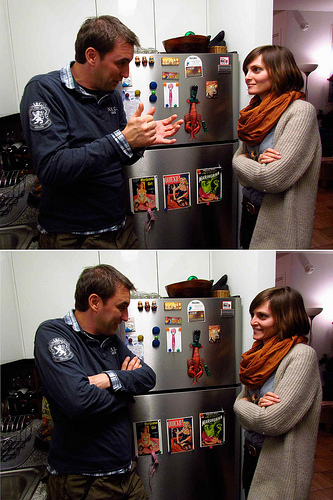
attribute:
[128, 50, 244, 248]
fridge — stainless steel, silver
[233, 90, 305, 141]
scarf — brown, burnt orange, loose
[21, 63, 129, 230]
shirt — blue, long-sleeve, dark blue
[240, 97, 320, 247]
cardigan — sand-colored, grey, long-sleeve, long, gray, ribbed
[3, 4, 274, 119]
cabinets — white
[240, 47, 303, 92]
hair — dark, short, brown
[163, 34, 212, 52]
basket — brown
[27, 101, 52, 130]
patch — blue, white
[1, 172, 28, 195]
strainer — metal